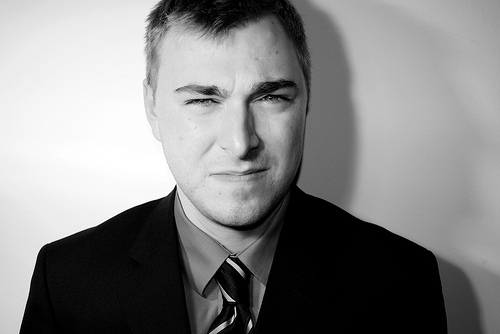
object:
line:
[224, 69, 242, 96]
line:
[246, 52, 267, 81]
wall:
[0, 1, 500, 333]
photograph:
[2, 0, 500, 333]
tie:
[203, 254, 257, 334]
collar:
[173, 193, 229, 300]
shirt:
[170, 195, 290, 332]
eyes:
[253, 91, 294, 108]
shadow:
[293, 1, 363, 212]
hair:
[147, 2, 313, 88]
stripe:
[222, 255, 249, 278]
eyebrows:
[173, 81, 232, 99]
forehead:
[168, 34, 293, 84]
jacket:
[19, 187, 450, 333]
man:
[22, 0, 447, 333]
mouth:
[209, 167, 271, 181]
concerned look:
[170, 62, 299, 193]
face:
[158, 30, 308, 229]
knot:
[213, 257, 254, 306]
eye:
[182, 96, 220, 110]